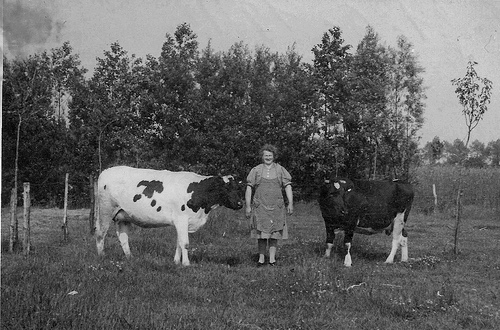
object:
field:
[2, 164, 499, 329]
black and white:
[163, 182, 203, 201]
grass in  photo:
[0, 165, 499, 328]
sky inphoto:
[4, 0, 499, 156]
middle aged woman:
[244, 145, 292, 268]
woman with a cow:
[93, 143, 293, 267]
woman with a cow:
[246, 144, 414, 268]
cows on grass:
[92, 163, 250, 267]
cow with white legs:
[383, 211, 405, 264]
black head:
[317, 179, 352, 218]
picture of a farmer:
[0, 0, 500, 329]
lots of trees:
[0, 21, 423, 207]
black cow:
[318, 176, 413, 265]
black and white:
[333, 179, 348, 194]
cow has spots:
[156, 205, 163, 213]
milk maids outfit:
[246, 163, 291, 240]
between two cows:
[242, 175, 320, 266]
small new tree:
[449, 60, 491, 255]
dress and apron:
[245, 162, 291, 240]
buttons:
[265, 173, 268, 178]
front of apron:
[253, 176, 290, 230]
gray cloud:
[0, 0, 500, 144]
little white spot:
[330, 182, 341, 189]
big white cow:
[90, 164, 244, 265]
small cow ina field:
[312, 170, 409, 266]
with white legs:
[172, 221, 190, 267]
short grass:
[0, 209, 500, 329]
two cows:
[94, 164, 414, 266]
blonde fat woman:
[244, 145, 293, 265]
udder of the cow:
[113, 212, 131, 226]